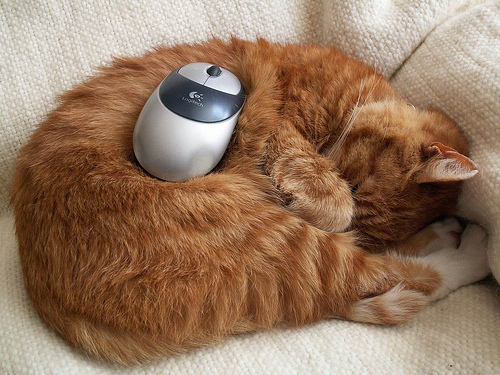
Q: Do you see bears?
A: No, there are no bears.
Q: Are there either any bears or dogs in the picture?
A: No, there are no bears or dogs.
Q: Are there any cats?
A: Yes, there is a cat.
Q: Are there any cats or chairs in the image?
A: Yes, there is a cat.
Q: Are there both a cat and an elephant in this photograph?
A: No, there is a cat but no elephants.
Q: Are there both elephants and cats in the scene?
A: No, there is a cat but no elephants.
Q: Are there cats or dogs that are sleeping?
A: Yes, the cat is sleeping.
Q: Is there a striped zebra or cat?
A: Yes, there is a striped cat.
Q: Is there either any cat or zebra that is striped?
A: Yes, the cat is striped.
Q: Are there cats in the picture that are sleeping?
A: Yes, there is a cat that is sleeping.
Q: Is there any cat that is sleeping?
A: Yes, there is a cat that is sleeping.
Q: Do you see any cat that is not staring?
A: Yes, there is a cat that is sleeping .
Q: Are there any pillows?
A: No, there are no pillows.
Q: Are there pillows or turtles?
A: No, there are no pillows or turtles.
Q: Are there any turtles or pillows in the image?
A: No, there are no pillows or turtles.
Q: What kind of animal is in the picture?
A: The animal is a cat.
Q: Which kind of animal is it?
A: The animal is a cat.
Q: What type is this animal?
A: This is a cat.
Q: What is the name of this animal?
A: This is a cat.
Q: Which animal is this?
A: This is a cat.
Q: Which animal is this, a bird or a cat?
A: This is a cat.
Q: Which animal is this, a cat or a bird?
A: This is a cat.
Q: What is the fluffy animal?
A: The animal is a cat.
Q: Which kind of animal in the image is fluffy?
A: The animal is a cat.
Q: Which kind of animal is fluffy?
A: The animal is a cat.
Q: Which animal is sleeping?
A: The animal is a cat.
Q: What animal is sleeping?
A: The animal is a cat.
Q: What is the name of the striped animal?
A: The animal is a cat.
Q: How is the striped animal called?
A: The animal is a cat.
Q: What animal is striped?
A: The animal is a cat.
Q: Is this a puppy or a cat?
A: This is a cat.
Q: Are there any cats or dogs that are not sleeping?
A: No, there is a cat but it is sleeping.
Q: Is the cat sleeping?
A: Yes, the cat is sleeping.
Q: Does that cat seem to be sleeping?
A: Yes, the cat is sleeping.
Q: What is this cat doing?
A: The cat is sleeping.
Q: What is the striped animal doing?
A: The cat is sleeping.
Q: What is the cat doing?
A: The cat is sleeping.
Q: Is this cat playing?
A: No, the cat is sleeping.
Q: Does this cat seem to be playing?
A: No, the cat is sleeping.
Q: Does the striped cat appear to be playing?
A: No, the cat is sleeping.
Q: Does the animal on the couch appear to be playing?
A: No, the cat is sleeping.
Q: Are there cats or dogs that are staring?
A: No, there is a cat but it is sleeping.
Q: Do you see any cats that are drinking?
A: No, there is a cat but it is sleeping.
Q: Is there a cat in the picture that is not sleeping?
A: No, there is a cat but it is sleeping.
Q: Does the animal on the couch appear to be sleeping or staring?
A: The cat is sleeping.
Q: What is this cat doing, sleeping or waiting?
A: The cat is sleeping.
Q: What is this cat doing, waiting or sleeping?
A: The cat is sleeping.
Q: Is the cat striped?
A: Yes, the cat is striped.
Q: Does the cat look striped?
A: Yes, the cat is striped.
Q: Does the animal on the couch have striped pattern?
A: Yes, the cat is striped.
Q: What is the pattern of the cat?
A: The cat is striped.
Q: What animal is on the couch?
A: The cat is on the couch.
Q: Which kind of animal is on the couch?
A: The animal is a cat.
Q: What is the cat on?
A: The cat is on the couch.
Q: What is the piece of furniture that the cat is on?
A: The piece of furniture is a couch.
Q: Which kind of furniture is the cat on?
A: The cat is on the couch.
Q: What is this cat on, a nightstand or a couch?
A: The cat is on a couch.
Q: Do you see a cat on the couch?
A: Yes, there is a cat on the couch.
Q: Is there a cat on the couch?
A: Yes, there is a cat on the couch.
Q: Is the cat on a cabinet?
A: No, the cat is on the couch.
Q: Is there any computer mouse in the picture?
A: Yes, there is a computer mouse.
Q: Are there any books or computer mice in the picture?
A: Yes, there is a computer mouse.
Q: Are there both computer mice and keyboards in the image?
A: No, there is a computer mouse but no keyboards.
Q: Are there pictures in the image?
A: No, there are no pictures.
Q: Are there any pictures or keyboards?
A: No, there are no pictures or keyboards.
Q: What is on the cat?
A: The mouse is on the cat.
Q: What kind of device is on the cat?
A: The device is a computer mouse.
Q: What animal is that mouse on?
A: The mouse is on the cat.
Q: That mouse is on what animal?
A: The mouse is on the cat.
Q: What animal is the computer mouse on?
A: The mouse is on the cat.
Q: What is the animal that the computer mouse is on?
A: The animal is a cat.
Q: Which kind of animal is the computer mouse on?
A: The computer mouse is on the cat.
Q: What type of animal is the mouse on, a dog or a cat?
A: The mouse is on a cat.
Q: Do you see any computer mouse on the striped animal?
A: Yes, there is a computer mouse on the cat.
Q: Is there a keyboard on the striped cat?
A: No, there is a computer mouse on the cat.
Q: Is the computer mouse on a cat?
A: Yes, the computer mouse is on a cat.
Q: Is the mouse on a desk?
A: No, the mouse is on a cat.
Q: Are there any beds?
A: No, there are no beds.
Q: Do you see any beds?
A: No, there are no beds.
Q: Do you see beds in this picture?
A: No, there are no beds.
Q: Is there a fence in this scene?
A: No, there are no fences.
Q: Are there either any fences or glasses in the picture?
A: No, there are no fences or glasses.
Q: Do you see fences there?
A: No, there are no fences.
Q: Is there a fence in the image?
A: No, there are no fences.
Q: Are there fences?
A: No, there are no fences.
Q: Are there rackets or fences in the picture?
A: No, there are no fences or rackets.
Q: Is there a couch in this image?
A: Yes, there is a couch.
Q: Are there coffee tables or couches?
A: Yes, there is a couch.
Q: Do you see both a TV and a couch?
A: No, there is a couch but no televisions.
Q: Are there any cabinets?
A: No, there are no cabinets.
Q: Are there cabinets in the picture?
A: No, there are no cabinets.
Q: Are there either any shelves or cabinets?
A: No, there are no cabinets or shelves.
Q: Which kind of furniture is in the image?
A: The furniture is a couch.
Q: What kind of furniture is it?
A: The piece of furniture is a couch.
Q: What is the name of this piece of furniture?
A: That is a couch.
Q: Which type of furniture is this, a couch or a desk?
A: That is a couch.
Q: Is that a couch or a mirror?
A: That is a couch.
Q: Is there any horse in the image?
A: No, there are no horses.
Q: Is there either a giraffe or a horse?
A: No, there are no horses or giraffes.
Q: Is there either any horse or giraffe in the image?
A: No, there are no horses or giraffes.